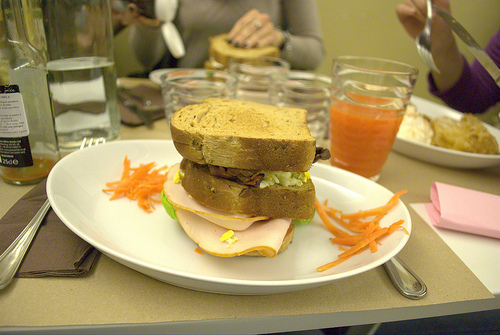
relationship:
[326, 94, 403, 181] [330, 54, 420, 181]
juice in glass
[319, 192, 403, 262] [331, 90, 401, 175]
carrots matching juice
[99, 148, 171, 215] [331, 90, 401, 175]
carrots matching juice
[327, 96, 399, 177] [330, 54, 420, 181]
orange beverage in glass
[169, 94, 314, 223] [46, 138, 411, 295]
sandwich in plate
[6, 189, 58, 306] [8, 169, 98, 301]
fork on napkin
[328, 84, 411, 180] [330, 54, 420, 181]
juice in glass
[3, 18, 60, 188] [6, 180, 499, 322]
bottle on table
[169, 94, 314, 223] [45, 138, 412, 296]
sandwich on plate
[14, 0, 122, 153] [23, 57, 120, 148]
glass with liquid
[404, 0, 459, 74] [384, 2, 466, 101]
fork in hand